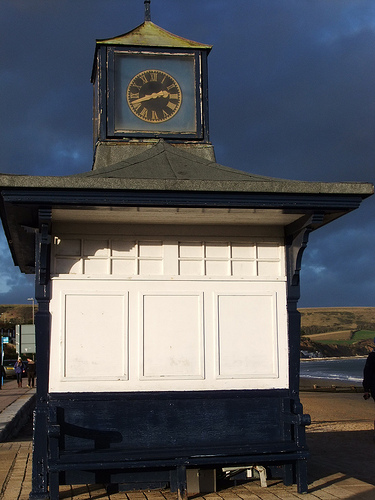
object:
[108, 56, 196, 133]
clock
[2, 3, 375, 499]
structure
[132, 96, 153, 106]
hand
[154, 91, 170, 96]
hand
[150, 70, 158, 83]
number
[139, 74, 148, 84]
number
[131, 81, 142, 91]
number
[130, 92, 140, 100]
number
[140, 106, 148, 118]
number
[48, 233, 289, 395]
wall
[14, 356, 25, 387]
person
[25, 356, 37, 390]
person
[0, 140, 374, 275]
roof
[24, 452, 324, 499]
base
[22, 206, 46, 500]
edge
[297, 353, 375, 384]
water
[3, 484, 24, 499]
brick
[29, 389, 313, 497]
bench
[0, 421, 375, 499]
floor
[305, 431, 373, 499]
shadow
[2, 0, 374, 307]
sky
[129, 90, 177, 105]
time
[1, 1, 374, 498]
picture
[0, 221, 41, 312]
part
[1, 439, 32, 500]
part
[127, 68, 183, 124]
part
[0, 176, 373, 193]
part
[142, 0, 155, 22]
tip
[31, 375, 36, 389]
part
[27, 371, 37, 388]
pant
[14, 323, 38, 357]
back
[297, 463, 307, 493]
part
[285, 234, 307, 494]
post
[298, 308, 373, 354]
mountain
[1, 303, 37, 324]
grass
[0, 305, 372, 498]
ground